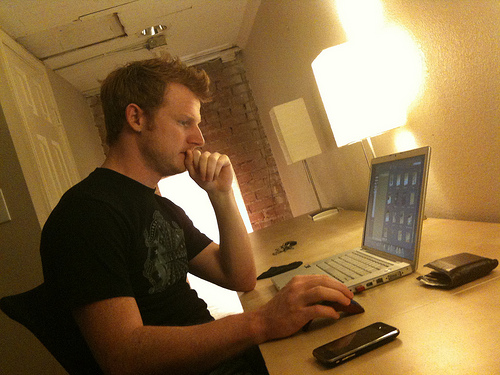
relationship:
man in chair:
[33, 58, 351, 375] [1, 278, 96, 375]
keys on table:
[269, 240, 301, 259] [216, 202, 497, 374]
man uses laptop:
[33, 58, 351, 375] [260, 146, 432, 305]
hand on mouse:
[268, 267, 354, 327] [291, 291, 366, 329]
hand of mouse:
[268, 267, 354, 327] [291, 291, 366, 329]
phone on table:
[302, 317, 402, 370] [216, 202, 497, 374]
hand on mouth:
[186, 147, 232, 190] [176, 149, 188, 158]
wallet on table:
[410, 248, 497, 294] [216, 202, 497, 374]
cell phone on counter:
[302, 317, 402, 370] [216, 202, 497, 374]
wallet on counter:
[410, 248, 497, 294] [216, 202, 497, 374]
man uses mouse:
[33, 58, 351, 375] [291, 291, 366, 329]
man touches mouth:
[33, 58, 351, 375] [176, 149, 188, 158]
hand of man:
[268, 267, 354, 327] [33, 58, 351, 375]